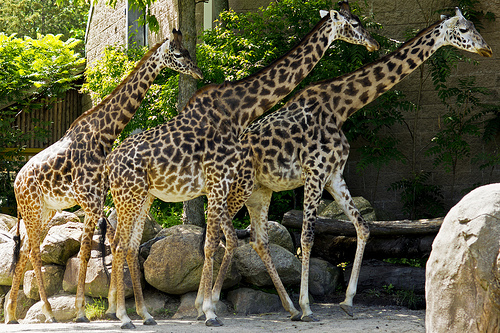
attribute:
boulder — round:
[426, 182, 497, 331]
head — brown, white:
[434, 7, 489, 57]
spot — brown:
[223, 96, 240, 110]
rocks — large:
[1, 203, 348, 329]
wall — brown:
[228, 1, 499, 218]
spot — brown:
[404, 58, 419, 70]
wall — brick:
[362, 78, 499, 197]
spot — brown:
[303, 111, 315, 125]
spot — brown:
[270, 134, 286, 152]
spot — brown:
[329, 81, 343, 94]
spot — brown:
[334, 104, 347, 119]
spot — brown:
[318, 90, 332, 103]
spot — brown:
[273, 122, 290, 138]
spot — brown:
[332, 90, 342, 110]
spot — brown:
[325, 78, 344, 94]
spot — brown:
[357, 88, 372, 106]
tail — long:
[94, 154, 110, 284]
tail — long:
[8, 199, 25, 279]